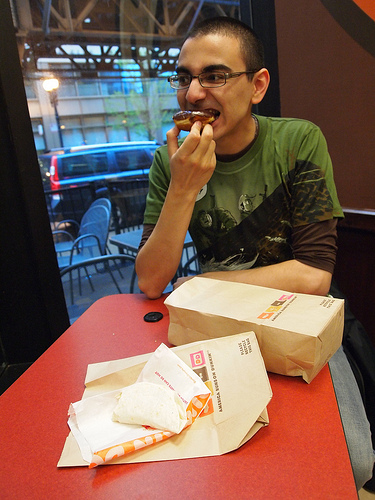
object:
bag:
[163, 272, 345, 383]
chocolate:
[173, 108, 211, 122]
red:
[81, 317, 119, 342]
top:
[21, 378, 75, 410]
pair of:
[173, 68, 256, 90]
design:
[192, 192, 255, 255]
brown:
[271, 300, 284, 308]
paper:
[164, 277, 346, 382]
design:
[255, 295, 299, 322]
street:
[40, 77, 65, 147]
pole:
[53, 102, 64, 151]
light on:
[42, 74, 61, 91]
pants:
[327, 348, 375, 491]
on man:
[155, 26, 337, 239]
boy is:
[135, 23, 375, 487]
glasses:
[167, 68, 256, 90]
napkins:
[111, 341, 212, 435]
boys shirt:
[138, 115, 344, 274]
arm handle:
[69, 234, 104, 263]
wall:
[276, 5, 375, 208]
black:
[198, 74, 218, 84]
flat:
[213, 421, 232, 448]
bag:
[57, 331, 271, 467]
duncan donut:
[187, 348, 224, 420]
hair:
[181, 16, 265, 81]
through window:
[61, 120, 85, 147]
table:
[0, 291, 358, 499]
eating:
[170, 102, 228, 132]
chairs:
[53, 204, 121, 304]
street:
[47, 172, 151, 237]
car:
[49, 145, 157, 228]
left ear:
[253, 69, 271, 103]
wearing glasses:
[173, 68, 253, 91]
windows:
[64, 160, 86, 176]